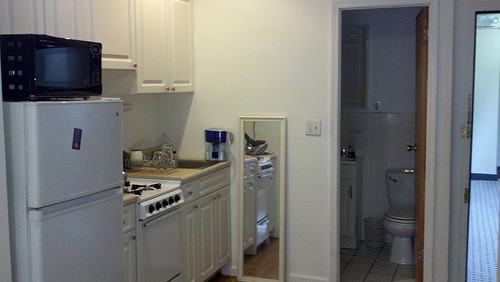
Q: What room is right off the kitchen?
A: Bathroom.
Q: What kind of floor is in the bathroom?
A: Tile.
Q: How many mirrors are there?
A: 1.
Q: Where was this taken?
A: Kitchen.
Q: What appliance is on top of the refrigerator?
A: Microwave.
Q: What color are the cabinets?
A: White.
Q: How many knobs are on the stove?
A: 5.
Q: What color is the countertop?
A: Brown.